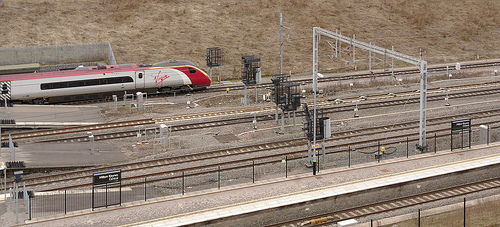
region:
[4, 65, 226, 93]
a red and silver train on the track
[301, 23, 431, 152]
metal structure that holds electrical wires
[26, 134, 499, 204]
fence separating platform from far track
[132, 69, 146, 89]
door on the side of the train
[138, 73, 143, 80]
window on the door of the train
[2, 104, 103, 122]
ramp beside the train on the track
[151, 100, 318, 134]
train track is made from metal and wood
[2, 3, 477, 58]
brown grass on the side of the hill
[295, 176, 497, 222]
train track on the bottom of the picture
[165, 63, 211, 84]
red white and yellow stripe on the front of the train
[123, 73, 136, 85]
a window on the train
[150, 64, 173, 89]
red writing on the train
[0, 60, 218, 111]
a red and silver train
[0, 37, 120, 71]
a cement wall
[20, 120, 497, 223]
a black metal fence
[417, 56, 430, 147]
a gray metal pole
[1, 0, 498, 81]
a black patch of dirt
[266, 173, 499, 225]
a pair of train tracks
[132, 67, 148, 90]
the door of a train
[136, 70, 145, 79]
a window on the train door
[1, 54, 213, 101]
a red and white train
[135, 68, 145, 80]
a window on the door of the train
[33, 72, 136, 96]
a row of windows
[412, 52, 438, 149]
a gray metal pole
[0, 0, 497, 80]
a brown dirt hill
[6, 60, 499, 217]
the train tracks for many trains at once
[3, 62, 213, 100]
part of a passenger train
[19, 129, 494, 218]
a fence next to the the train tracks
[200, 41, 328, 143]
poles next to the tracks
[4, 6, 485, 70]
the hill next to the track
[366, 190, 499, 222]
another fence in the corner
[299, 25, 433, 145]
a tall metal pole covering some train tracks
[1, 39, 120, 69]
another fence next to the train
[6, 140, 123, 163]
a ramp in between the tracks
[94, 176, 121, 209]
a gate in the fence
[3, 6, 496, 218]
Photo was taken in the daytime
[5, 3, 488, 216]
Photo was taken outdoors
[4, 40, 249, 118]
Train is on the train tracks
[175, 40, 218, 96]
End of the train is red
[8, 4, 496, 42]
Grass is brown in color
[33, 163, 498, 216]
Fence is in the foreground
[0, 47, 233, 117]
Side view of a train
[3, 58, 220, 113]
Train is gray in color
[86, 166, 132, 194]
A black sign is in the foreground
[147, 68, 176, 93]
Train has red writing on the side